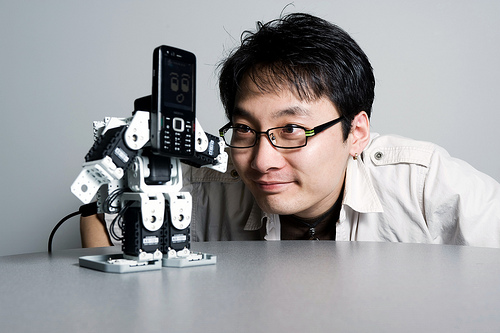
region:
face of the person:
[240, 54, 357, 248]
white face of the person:
[241, 102, 344, 217]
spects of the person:
[218, 113, 323, 150]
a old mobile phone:
[150, 40, 205, 160]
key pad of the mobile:
[159, 119, 195, 151]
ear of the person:
[344, 112, 371, 160]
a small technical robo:
[92, 93, 234, 298]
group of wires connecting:
[92, 182, 151, 254]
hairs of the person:
[232, 28, 372, 91]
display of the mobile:
[159, 50, 204, 112]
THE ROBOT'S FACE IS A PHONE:
[161, 62, 193, 114]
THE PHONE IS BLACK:
[148, 37, 203, 159]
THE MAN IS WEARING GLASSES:
[214, 100, 353, 151]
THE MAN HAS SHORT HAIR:
[216, 7, 379, 147]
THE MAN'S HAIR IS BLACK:
[211, 7, 377, 154]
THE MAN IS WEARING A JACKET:
[93, 117, 499, 252]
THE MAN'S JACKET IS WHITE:
[93, 119, 496, 257]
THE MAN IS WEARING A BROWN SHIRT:
[269, 195, 344, 247]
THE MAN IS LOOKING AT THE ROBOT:
[64, 7, 499, 255]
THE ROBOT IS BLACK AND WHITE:
[68, 40, 233, 276]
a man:
[241, 45, 382, 260]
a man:
[290, 147, 370, 241]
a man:
[248, 120, 358, 227]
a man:
[291, 144, 328, 268]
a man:
[272, 137, 350, 312]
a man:
[204, 87, 335, 247]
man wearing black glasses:
[201, 12, 384, 252]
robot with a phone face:
[70, 30, 235, 285]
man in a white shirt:
[197, 17, 487, 267]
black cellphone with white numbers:
[135, 25, 197, 161]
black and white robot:
[75, 26, 227, 327]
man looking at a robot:
[72, 0, 432, 275]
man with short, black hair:
[217, 13, 371, 233]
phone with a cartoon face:
[121, 24, 220, 168]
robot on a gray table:
[20, 40, 237, 328]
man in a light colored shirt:
[216, 19, 498, 259]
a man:
[279, 80, 414, 222]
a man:
[250, 65, 402, 178]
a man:
[228, 34, 342, 169]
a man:
[273, 123, 381, 203]